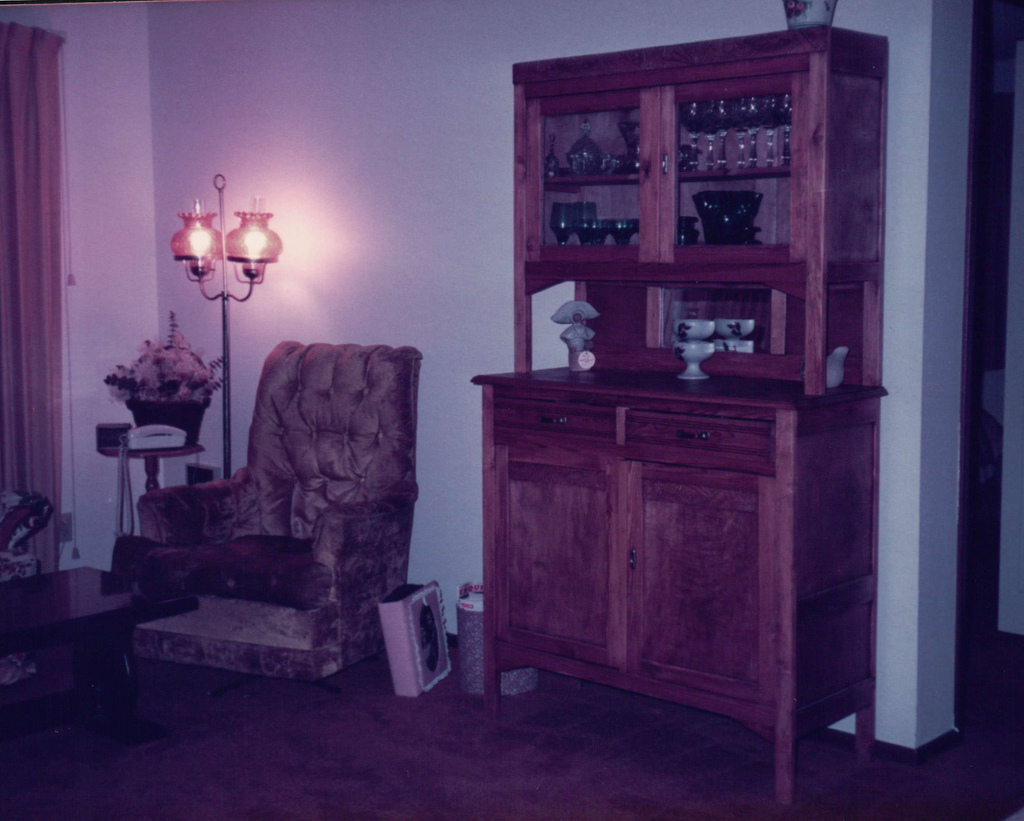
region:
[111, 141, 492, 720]
The chair is next to the lamp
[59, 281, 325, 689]
A pot of flowers is on the table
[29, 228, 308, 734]
The white phone has a cord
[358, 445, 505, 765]
A photo album is on the floor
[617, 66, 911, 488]
Glasses in the wooden cabinet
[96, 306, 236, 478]
The flowers in the pot are pink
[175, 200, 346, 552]
The lamp is on a metal pole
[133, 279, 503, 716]
The chair is brown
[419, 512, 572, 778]
A trash can is on the floor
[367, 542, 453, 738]
book sitting in on the floor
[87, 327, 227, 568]
basket of flowers sitting on a small table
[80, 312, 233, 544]
white telephone sitting on a small table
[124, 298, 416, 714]
tan chair sitting against white wall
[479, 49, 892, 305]
dishes in a cabinet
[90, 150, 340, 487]
lit lamp behind a small table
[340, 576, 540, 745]
pink book sitting in the floor beside garbage can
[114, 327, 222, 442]
a basket of flowers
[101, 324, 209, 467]
a basket of flowers on a table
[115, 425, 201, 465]
a white phone on a table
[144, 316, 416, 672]
a chair with a cushion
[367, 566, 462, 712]
a photo album on a the floor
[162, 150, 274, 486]
a tall floor lamp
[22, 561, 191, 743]
a square wood table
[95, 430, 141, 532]
a white phone cord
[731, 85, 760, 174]
a tall glass on a shelf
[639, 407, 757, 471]
drawer on the cabinet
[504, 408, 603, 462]
drawer on the cabinet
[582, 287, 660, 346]
drawer on the cabinet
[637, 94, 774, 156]
drawer on the cabinet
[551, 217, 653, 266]
drawer on the cabinet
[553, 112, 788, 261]
several dishes on a shelves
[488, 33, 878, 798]
a tall wood cabinet with drawers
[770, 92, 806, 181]
A vessel made for drinking.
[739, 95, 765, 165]
A vessel made for drinking.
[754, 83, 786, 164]
A vessel made for drinking.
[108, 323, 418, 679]
a chair that you sit in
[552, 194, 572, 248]
a vessel made for drinking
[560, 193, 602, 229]
a vessel made for drinking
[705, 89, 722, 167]
a vessel made for drinking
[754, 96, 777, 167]
a vessel made for drinking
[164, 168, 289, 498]
Floor lamp.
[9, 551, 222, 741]
A wooden cofee table.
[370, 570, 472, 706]
A scrapbook by the chair.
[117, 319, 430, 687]
A large chair.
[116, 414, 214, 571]
A corded, land line phone.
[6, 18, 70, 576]
Curtains cover a window.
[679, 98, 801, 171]
Glasses in a cabinet.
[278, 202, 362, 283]
Light from the lamp reflecting off the wall.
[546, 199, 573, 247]
A glass in a cabinet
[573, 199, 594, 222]
A glass in a cabinet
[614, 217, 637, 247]
A glass in a cabinet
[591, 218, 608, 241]
A glass in a cabinet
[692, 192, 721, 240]
A glass in a cabinet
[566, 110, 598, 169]
A glass in a cabinet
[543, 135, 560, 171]
A glass in a cabinet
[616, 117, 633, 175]
A glass in a cabinet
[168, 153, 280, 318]
lamp near a wall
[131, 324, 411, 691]
A gold velvet recliner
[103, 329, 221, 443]
A flower arrangement on a table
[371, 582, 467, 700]
A thick white book